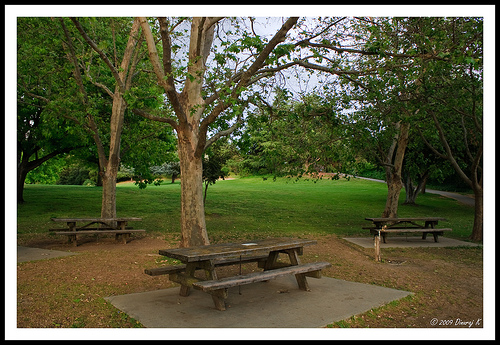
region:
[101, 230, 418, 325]
picnic table on concrete slab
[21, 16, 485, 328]
scene of a park with tables and trees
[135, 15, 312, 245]
large hard wood tree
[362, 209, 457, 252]
picnic table on a concrete slab in a park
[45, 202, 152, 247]
picnic table sitting in a patch of dirt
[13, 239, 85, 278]
concrete slab in a park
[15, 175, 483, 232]
large grassy field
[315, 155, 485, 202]
sidewalk running along the side of the park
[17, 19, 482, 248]
many large green leafy trees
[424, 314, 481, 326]
copyright and date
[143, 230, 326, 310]
old well worn faded wooden picnic bench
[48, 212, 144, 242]
old well worn faded wooden picnic bench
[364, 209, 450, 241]
old well worn faded wooden picnic bench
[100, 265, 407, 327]
grey concrete rectangle platform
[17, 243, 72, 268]
grey concrete rectangle platform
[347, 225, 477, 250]
grey concrete rectangle platform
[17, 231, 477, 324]
picnic area of grass and dirt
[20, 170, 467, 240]
field of green cut grass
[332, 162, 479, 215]
grey paved walkway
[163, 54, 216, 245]
light brown wide tree trunk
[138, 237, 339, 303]
brown bench in the park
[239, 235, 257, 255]
white piece of paper on table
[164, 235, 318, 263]
picnic table under tree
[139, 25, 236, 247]
tree next to pic nic table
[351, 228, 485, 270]
patio under table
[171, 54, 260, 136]
green leaves on the tree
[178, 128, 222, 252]
dead bark on the tree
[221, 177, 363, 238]
patch of grass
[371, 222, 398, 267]
stick sticking out from the ground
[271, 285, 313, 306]
hole in patio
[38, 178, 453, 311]
three tables three adjacent trees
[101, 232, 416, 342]
picnic table with concrete base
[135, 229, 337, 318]
table with one white item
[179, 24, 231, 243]
a tree peeking out from a tree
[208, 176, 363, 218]
a field designed for play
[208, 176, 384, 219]
a place for frisbee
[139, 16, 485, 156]
sky among the limbs and leaves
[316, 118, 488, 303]
a road on the edge of the park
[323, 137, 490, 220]
a street on the left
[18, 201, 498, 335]
three tables, two on concrete pads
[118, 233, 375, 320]
Picnic table made from wood.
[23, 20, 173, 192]
Leaves on rhe tree are green.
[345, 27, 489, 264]
Tree shades table below.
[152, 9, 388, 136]
The sky is blue and clear.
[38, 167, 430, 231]
Grass is lush and green.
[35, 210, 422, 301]
Grass around tables has been worn away.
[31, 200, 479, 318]
The park is empty.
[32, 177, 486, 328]
Picnic area is clean.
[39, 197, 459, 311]
Tables show signs of wear.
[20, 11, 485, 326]
The park is desserted.